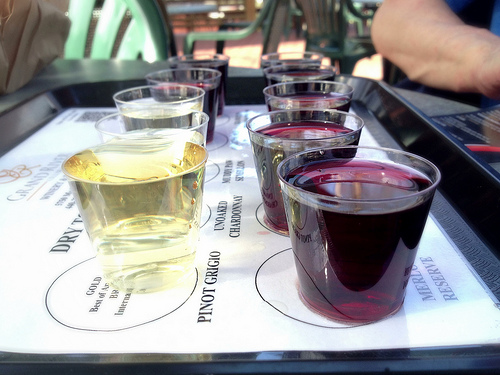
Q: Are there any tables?
A: Yes, there is a table.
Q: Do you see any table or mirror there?
A: Yes, there is a table.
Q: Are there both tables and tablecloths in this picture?
A: No, there is a table but no tablecloths.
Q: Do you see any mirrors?
A: No, there are no mirrors.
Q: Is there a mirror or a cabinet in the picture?
A: No, there are no mirrors or cabinets.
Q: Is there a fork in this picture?
A: No, there are no forks.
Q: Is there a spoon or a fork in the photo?
A: No, there are no forks or spoons.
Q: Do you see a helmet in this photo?
A: No, there are no helmets.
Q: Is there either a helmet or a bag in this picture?
A: No, there are no helmets or bags.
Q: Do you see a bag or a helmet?
A: No, there are no helmets or bags.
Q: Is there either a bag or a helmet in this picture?
A: No, there are no helmets or bags.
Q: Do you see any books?
A: No, there are no books.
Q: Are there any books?
A: No, there are no books.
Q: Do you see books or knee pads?
A: No, there are no books or knee pads.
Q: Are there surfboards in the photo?
A: No, there are no surfboards.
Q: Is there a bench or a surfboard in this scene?
A: No, there are no surfboards or benches.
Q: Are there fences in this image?
A: No, there are no fences.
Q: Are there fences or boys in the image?
A: No, there are no fences or boys.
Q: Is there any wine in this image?
A: Yes, there is wine.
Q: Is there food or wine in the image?
A: Yes, there is wine.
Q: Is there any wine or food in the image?
A: Yes, there is wine.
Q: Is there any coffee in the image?
A: No, there is no coffee.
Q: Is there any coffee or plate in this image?
A: No, there are no coffee or plates.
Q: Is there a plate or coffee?
A: No, there are no coffee or plates.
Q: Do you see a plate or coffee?
A: No, there are no coffee or plates.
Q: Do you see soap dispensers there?
A: No, there are no soap dispensers.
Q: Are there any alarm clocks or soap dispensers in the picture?
A: No, there are no soap dispensers or alarm clocks.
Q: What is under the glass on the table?
A: The mat is under the glass.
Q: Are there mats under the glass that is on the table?
A: Yes, there is a mat under the glass.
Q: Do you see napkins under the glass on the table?
A: No, there is a mat under the glass.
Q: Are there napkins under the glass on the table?
A: No, there is a mat under the glass.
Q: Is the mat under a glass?
A: Yes, the mat is under a glass.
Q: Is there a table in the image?
A: Yes, there is a table.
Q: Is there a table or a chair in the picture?
A: Yes, there is a table.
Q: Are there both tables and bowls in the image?
A: No, there is a table but no bowls.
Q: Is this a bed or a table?
A: This is a table.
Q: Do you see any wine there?
A: Yes, there is wine.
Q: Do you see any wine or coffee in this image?
A: Yes, there is wine.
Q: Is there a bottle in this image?
A: No, there are no bottles.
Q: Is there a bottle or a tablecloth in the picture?
A: No, there are no bottles or tablecloths.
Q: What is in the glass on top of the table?
A: The wine is in the glass.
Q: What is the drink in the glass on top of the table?
A: The drink is wine.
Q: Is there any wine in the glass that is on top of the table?
A: Yes, there is wine in the glass.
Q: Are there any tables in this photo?
A: Yes, there is a table.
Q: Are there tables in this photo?
A: Yes, there is a table.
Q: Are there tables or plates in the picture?
A: Yes, there is a table.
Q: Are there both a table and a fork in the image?
A: No, there is a table but no forks.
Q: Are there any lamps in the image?
A: No, there are no lamps.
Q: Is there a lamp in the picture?
A: No, there are no lamps.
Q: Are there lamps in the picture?
A: No, there are no lamps.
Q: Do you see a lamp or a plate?
A: No, there are no lamps or plates.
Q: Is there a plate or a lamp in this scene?
A: No, there are no lamps or plates.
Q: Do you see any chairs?
A: Yes, there is a chair.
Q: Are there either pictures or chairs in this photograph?
A: Yes, there is a chair.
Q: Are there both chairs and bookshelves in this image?
A: No, there is a chair but no bookshelves.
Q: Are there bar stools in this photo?
A: No, there are no bar stools.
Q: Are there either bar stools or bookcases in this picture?
A: No, there are no bar stools or bookcases.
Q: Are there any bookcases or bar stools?
A: No, there are no bar stools or bookcases.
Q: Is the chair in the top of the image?
A: Yes, the chair is in the top of the image.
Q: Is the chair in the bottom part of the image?
A: No, the chair is in the top of the image.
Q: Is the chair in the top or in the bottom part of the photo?
A: The chair is in the top of the image.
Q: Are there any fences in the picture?
A: No, there are no fences.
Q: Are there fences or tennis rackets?
A: No, there are no fences or tennis rackets.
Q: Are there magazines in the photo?
A: No, there are no magazines.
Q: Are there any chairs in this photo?
A: Yes, there is a chair.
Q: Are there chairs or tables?
A: Yes, there is a chair.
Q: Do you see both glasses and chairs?
A: Yes, there are both a chair and glasses.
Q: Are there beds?
A: No, there are no beds.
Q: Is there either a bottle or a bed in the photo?
A: No, there are no beds or bottles.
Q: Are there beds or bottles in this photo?
A: No, there are no beds or bottles.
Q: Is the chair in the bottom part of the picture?
A: No, the chair is in the top of the image.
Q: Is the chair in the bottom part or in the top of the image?
A: The chair is in the top of the image.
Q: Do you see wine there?
A: Yes, there is wine.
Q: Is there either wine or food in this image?
A: Yes, there is wine.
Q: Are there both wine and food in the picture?
A: No, there is wine but no food.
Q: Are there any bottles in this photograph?
A: No, there are no bottles.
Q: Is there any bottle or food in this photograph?
A: No, there are no bottles or food.